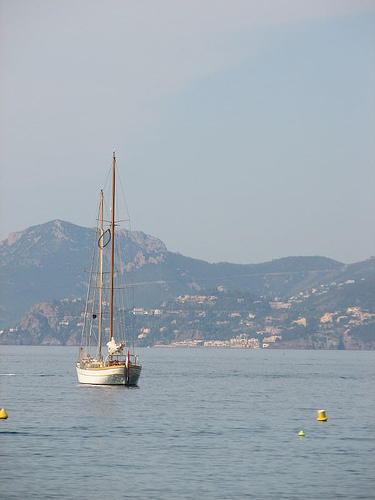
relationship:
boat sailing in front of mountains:
[77, 154, 141, 387] [2, 217, 371, 357]